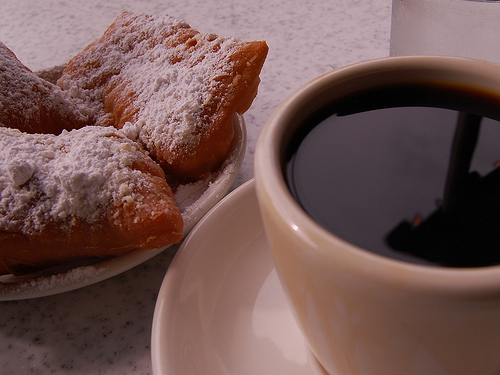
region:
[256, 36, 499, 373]
Tan cup of dark liquid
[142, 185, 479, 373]
Small circle saucer for cup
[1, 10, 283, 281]
Three pieces of bread items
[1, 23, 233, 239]
White powder on bread items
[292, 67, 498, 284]
Coffee in tan cup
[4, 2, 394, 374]
Food on white table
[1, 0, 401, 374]
black spots on table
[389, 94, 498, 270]
Reflection in coffee cup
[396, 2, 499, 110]
White part of floor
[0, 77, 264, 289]
Bread items on white plate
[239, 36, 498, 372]
a cup of coffee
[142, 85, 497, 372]
a white plate on table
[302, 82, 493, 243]
reflections in the coffee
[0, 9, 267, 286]
a plate of pastry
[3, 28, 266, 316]
a pastry on a plate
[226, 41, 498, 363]
cup of black coffee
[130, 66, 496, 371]
a white plate on a table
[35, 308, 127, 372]
a dotted table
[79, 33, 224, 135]
sweet powder on a pastry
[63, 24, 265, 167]
donut on a plate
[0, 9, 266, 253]
Powered treats sit on a plate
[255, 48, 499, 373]
A cup of coffee placed on a saucer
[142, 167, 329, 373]
A saucer with a cup on it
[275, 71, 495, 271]
The coffee inside the cup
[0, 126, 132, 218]
The powder on top of the pastery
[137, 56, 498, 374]
A cup of cofee with the saucer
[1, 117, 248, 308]
The white plate which holds the pasteries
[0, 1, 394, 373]
The white speckled table top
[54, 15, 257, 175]
One powdered pastry treat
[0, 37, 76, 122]
A pastry treat next to other pastry treats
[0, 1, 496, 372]
a scene of morning breakfast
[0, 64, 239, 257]
pastries in upper right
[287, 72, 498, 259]
black coffee is left of image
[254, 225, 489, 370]
black coffee in a brown cup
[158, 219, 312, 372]
coffee sits on a white saucer plate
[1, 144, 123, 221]
powdered sugar on pastry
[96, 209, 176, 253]
brown crusted part of pastry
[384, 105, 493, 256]
there is a reflection in the coffee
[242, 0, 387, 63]
breakfast on a marble style surface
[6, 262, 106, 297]
powdered sugar fallen on plate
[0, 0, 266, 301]
powdered pastries on a white dish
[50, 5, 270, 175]
powdered pastry on a plate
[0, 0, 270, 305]
three pastries on a white plate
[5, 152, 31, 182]
ball of powdered sugar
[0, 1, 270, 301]
pastries topped with powdered sugar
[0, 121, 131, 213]
powder sugar topping on a pastry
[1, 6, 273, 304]
pastries on a plate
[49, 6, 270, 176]
pastry on a dish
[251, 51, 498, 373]
cup of coffee